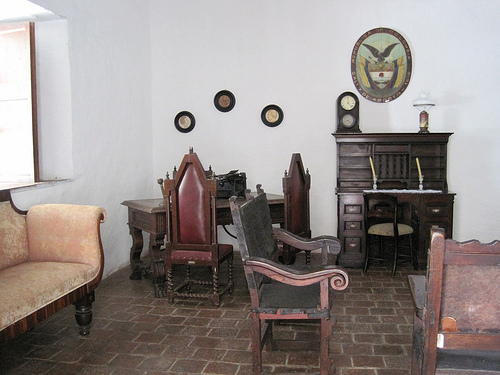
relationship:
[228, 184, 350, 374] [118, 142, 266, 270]
chair in desk area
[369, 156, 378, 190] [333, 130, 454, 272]
candle in desk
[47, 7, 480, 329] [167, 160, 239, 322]
room in chair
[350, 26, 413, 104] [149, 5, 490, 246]
frame in wall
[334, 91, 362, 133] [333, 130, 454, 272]
clock in desk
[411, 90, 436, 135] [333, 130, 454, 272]
lamp in desk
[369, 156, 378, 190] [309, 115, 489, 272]
candle sitting on desk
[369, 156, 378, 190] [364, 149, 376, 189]
candle resting in candlestick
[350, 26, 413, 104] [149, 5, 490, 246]
frame hanging on wall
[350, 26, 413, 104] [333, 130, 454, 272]
frame hanging above desk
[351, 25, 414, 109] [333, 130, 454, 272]
frame hanging above desk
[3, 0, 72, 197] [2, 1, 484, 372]
window adorning room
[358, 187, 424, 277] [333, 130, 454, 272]
chair sitting in front of desk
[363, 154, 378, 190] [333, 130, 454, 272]
candle sitting on top of desk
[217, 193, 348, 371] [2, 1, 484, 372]
chair sitting inside room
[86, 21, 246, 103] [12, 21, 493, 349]
wall supporting room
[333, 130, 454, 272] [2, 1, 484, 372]
desk sitting inside room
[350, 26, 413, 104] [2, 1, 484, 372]
frame hanging in room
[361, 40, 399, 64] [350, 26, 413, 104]
eagle depicted in frame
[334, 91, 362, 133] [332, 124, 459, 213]
clock sitting on top of desk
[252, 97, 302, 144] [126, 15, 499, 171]
black record hanging on wall